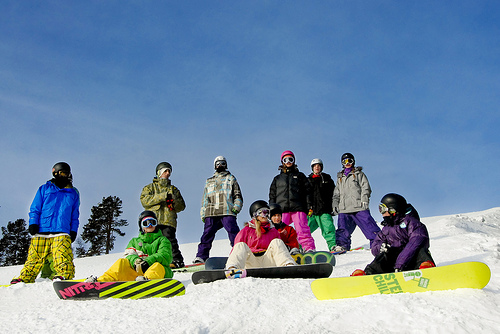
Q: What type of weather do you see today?
A: It is clear.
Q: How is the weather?
A: It is clear.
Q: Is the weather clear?
A: Yes, it is clear.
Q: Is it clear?
A: Yes, it is clear.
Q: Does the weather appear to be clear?
A: Yes, it is clear.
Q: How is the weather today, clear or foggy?
A: It is clear.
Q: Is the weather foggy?
A: No, it is clear.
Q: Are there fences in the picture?
A: No, there are no fences.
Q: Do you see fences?
A: No, there are no fences.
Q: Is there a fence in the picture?
A: No, there are no fences.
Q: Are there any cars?
A: No, there are no cars.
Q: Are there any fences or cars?
A: No, there are no cars or fences.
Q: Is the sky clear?
A: Yes, the sky is clear.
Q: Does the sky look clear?
A: Yes, the sky is clear.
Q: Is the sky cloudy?
A: No, the sky is clear.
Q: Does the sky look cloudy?
A: No, the sky is clear.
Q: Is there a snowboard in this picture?
A: Yes, there is a snowboard.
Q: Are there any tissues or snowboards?
A: Yes, there is a snowboard.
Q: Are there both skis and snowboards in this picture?
A: No, there is a snowboard but no skis.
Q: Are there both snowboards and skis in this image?
A: No, there is a snowboard but no skis.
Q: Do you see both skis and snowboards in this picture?
A: No, there is a snowboard but no skis.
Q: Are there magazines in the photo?
A: No, there are no magazines.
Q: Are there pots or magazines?
A: No, there are no magazines or pots.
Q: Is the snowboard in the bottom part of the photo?
A: Yes, the snowboard is in the bottom of the image.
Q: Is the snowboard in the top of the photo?
A: No, the snowboard is in the bottom of the image.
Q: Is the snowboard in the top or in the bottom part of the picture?
A: The snowboard is in the bottom of the image.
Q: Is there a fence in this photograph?
A: No, there are no fences.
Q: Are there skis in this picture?
A: No, there are no skis.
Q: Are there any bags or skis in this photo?
A: No, there are no skis or bags.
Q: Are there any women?
A: Yes, there is a woman.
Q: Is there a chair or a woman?
A: Yes, there is a woman.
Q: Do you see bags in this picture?
A: No, there are no bags.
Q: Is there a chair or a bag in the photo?
A: No, there are no bags or chairs.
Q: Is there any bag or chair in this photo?
A: No, there are no bags or chairs.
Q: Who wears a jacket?
A: The woman wears a jacket.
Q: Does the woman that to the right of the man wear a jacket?
A: Yes, the woman wears a jacket.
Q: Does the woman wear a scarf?
A: No, the woman wears a jacket.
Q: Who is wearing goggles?
A: The woman is wearing goggles.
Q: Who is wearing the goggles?
A: The woman is wearing goggles.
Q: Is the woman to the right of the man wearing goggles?
A: Yes, the woman is wearing goggles.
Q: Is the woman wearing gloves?
A: No, the woman is wearing goggles.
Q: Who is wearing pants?
A: The woman is wearing pants.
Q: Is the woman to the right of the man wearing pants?
A: Yes, the woman is wearing pants.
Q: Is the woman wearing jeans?
A: No, the woman is wearing pants.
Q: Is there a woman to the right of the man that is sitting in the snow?
A: Yes, there is a woman to the right of the man.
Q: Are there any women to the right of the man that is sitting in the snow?
A: Yes, there is a woman to the right of the man.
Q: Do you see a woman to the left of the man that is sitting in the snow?
A: No, the woman is to the right of the man.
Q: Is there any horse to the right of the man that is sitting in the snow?
A: No, there is a woman to the right of the man.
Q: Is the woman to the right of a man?
A: Yes, the woman is to the right of a man.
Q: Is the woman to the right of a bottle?
A: No, the woman is to the right of a man.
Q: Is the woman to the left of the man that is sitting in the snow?
A: No, the woman is to the right of the man.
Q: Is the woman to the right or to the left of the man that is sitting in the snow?
A: The woman is to the right of the man.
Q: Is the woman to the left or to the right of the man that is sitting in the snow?
A: The woman is to the right of the man.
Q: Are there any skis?
A: No, there are no skis.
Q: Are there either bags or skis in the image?
A: No, there are no skis or bags.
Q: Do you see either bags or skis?
A: No, there are no skis or bags.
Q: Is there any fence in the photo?
A: No, there are no fences.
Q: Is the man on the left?
A: Yes, the man is on the left of the image.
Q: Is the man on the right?
A: No, the man is on the left of the image.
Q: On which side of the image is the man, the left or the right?
A: The man is on the left of the image.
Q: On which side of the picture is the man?
A: The man is on the left of the image.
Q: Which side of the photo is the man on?
A: The man is on the left of the image.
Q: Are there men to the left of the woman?
A: Yes, there is a man to the left of the woman.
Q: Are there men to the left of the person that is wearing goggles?
A: Yes, there is a man to the left of the woman.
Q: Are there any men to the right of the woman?
A: No, the man is to the left of the woman.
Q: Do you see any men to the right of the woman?
A: No, the man is to the left of the woman.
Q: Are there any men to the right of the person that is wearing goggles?
A: No, the man is to the left of the woman.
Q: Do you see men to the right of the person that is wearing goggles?
A: No, the man is to the left of the woman.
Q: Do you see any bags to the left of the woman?
A: No, there is a man to the left of the woman.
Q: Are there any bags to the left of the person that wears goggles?
A: No, there is a man to the left of the woman.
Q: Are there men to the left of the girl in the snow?
A: Yes, there is a man to the left of the girl.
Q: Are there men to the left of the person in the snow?
A: Yes, there is a man to the left of the girl.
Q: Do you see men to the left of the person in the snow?
A: Yes, there is a man to the left of the girl.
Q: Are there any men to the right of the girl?
A: No, the man is to the left of the girl.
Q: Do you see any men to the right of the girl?
A: No, the man is to the left of the girl.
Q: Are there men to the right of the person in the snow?
A: No, the man is to the left of the girl.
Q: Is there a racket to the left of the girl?
A: No, there is a man to the left of the girl.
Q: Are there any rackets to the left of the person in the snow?
A: No, there is a man to the left of the girl.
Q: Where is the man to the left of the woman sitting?
A: The man is sitting in the snow.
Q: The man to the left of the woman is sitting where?
A: The man is sitting in the snow.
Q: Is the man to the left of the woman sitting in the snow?
A: Yes, the man is sitting in the snow.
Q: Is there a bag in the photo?
A: No, there are no bags.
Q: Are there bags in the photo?
A: No, there are no bags.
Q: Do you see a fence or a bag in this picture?
A: No, there are no bags or fences.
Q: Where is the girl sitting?
A: The girl is sitting in the snow.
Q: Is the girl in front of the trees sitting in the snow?
A: Yes, the girl is sitting in the snow.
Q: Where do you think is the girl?
A: The girl is in the snow.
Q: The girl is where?
A: The girl is in the snow.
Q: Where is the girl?
A: The girl is in the snow.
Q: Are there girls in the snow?
A: Yes, there is a girl in the snow.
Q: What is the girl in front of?
A: The girl is in front of the trees.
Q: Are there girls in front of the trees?
A: Yes, there is a girl in front of the trees.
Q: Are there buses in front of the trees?
A: No, there is a girl in front of the trees.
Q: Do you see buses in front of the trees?
A: No, there is a girl in front of the trees.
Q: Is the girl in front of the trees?
A: Yes, the girl is in front of the trees.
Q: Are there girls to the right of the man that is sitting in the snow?
A: Yes, there is a girl to the right of the man.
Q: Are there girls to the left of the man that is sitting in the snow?
A: No, the girl is to the right of the man.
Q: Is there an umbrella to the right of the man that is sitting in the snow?
A: No, there is a girl to the right of the man.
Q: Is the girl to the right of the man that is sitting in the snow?
A: Yes, the girl is to the right of the man.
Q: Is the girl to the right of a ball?
A: No, the girl is to the right of the man.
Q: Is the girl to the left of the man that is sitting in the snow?
A: No, the girl is to the right of the man.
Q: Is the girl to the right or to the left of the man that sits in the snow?
A: The girl is to the right of the man.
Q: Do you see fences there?
A: No, there are no fences.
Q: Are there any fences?
A: No, there are no fences.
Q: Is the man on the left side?
A: Yes, the man is on the left of the image.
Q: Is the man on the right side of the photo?
A: No, the man is on the left of the image.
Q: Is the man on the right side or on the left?
A: The man is on the left of the image.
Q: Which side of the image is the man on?
A: The man is on the left of the image.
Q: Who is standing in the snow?
A: The man is standing in the snow.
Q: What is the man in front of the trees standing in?
A: The man is standing in the snow.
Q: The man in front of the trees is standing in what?
A: The man is standing in the snow.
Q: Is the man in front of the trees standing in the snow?
A: Yes, the man is standing in the snow.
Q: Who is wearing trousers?
A: The man is wearing trousers.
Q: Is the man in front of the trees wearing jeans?
A: No, the man is wearing trousers.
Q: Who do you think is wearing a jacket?
A: The man is wearing a jacket.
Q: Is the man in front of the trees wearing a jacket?
A: Yes, the man is wearing a jacket.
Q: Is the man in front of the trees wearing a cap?
A: No, the man is wearing a jacket.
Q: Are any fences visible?
A: No, there are no fences.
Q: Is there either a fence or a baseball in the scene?
A: No, there are no fences or baseballs.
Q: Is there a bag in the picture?
A: No, there are no bags.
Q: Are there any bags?
A: No, there are no bags.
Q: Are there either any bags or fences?
A: No, there are no bags or fences.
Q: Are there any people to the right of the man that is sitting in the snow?
A: Yes, there is a person to the right of the man.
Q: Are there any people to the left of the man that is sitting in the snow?
A: No, the person is to the right of the man.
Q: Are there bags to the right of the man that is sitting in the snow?
A: No, there is a person to the right of the man.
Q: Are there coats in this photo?
A: Yes, there is a coat.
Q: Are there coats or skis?
A: Yes, there is a coat.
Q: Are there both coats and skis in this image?
A: No, there is a coat but no skis.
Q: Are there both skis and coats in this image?
A: No, there is a coat but no skis.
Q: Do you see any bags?
A: No, there are no bags.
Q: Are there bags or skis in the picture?
A: No, there are no bags or skis.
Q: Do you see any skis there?
A: No, there are no skis.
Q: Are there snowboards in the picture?
A: Yes, there is a snowboard.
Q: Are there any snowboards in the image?
A: Yes, there is a snowboard.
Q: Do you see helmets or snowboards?
A: Yes, there is a snowboard.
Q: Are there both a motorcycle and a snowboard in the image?
A: No, there is a snowboard but no motorcycles.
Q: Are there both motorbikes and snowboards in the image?
A: No, there is a snowboard but no motorcycles.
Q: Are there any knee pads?
A: No, there are no knee pads.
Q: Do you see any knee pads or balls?
A: No, there are no knee pads or balls.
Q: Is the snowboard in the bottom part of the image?
A: Yes, the snowboard is in the bottom of the image.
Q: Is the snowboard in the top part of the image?
A: No, the snowboard is in the bottom of the image.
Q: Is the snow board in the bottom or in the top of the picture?
A: The snow board is in the bottom of the image.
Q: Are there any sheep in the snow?
A: No, there is a snowboard in the snow.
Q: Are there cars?
A: No, there are no cars.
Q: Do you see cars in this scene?
A: No, there are no cars.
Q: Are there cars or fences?
A: No, there are no cars or fences.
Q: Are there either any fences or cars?
A: No, there are no cars or fences.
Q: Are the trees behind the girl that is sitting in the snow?
A: Yes, the trees are behind the girl.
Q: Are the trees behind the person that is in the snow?
A: Yes, the trees are behind the girl.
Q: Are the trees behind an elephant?
A: No, the trees are behind the girl.